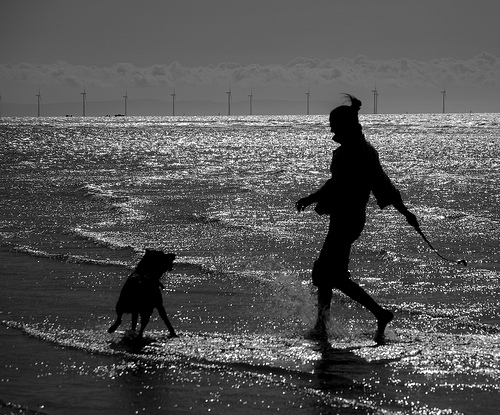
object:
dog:
[107, 248, 183, 342]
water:
[1, 117, 496, 413]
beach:
[0, 113, 499, 414]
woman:
[293, 92, 420, 344]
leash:
[409, 218, 466, 268]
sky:
[0, 0, 500, 111]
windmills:
[223, 87, 238, 113]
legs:
[109, 305, 124, 332]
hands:
[295, 196, 315, 211]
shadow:
[300, 340, 423, 407]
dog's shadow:
[107, 328, 165, 355]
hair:
[329, 92, 364, 126]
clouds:
[6, 52, 499, 88]